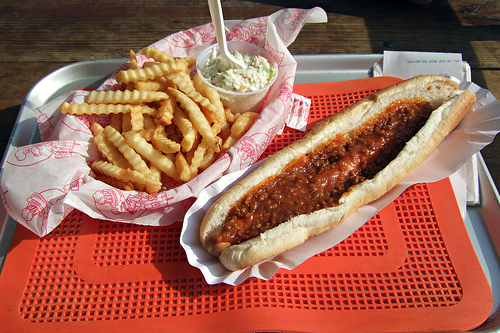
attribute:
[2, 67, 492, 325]
mat — red, rubber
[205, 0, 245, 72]
fork — plastic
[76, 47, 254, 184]
french fries — golden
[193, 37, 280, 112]
ramikin — small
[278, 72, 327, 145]
salt — red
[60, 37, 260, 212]
fries — crinkle cut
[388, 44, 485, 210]
napkins — white, stack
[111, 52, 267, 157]
fries — french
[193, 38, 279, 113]
ramekin — plastic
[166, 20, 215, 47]
pattern — red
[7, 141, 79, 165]
pattern — red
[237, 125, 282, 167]
pattern — red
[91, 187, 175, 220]
pattern — red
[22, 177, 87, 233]
pattern — red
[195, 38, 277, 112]
container — small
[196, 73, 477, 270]
bun — hot dog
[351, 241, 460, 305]
place mat — orange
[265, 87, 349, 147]
packet — salt, single serving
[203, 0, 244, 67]
fork — white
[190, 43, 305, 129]
bowl — small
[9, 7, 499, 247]
picnic table — brown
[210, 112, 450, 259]
hot dog — foot long, chili, sandwich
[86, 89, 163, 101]
fry — crinkle cut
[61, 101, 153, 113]
fry — crinkle cut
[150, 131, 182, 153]
fry — crinkle cut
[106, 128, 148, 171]
fry — crinkle cut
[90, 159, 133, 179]
fry — crinkle cut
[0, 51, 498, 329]
tray — metal, silver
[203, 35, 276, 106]
slaw — cole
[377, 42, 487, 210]
receipt — paper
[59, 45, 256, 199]
fries — crinkle cut